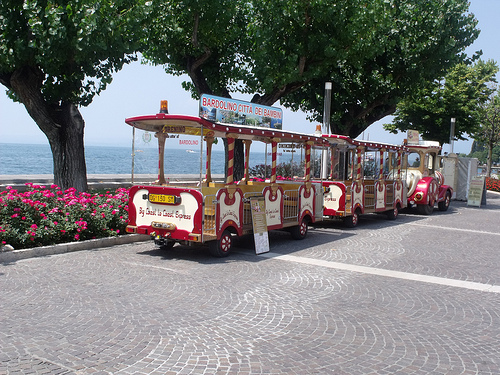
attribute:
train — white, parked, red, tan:
[172, 136, 278, 243]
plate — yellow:
[148, 195, 187, 209]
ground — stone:
[59, 283, 148, 319]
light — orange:
[156, 102, 173, 114]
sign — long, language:
[210, 89, 294, 128]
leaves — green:
[76, 47, 90, 51]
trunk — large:
[59, 168, 95, 196]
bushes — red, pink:
[0, 205, 98, 231]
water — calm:
[109, 158, 131, 168]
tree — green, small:
[17, 123, 95, 144]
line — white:
[320, 262, 325, 264]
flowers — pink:
[6, 186, 45, 204]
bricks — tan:
[40, 286, 104, 315]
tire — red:
[203, 232, 242, 254]